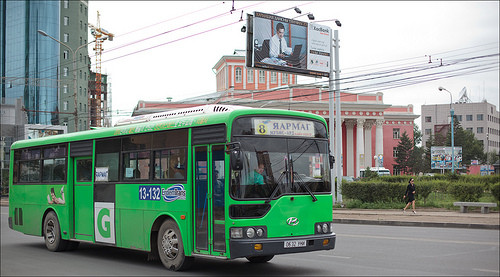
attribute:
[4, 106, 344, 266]
bus — green, long, big, wide, running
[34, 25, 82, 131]
light — tall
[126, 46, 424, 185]
building — red, orange, wide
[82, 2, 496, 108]
sky — white, gray, big, grey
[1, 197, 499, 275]
road — grey, long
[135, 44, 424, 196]
building — pink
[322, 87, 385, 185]
columns — white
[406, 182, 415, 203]
dress — black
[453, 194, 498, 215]
bench — concrete